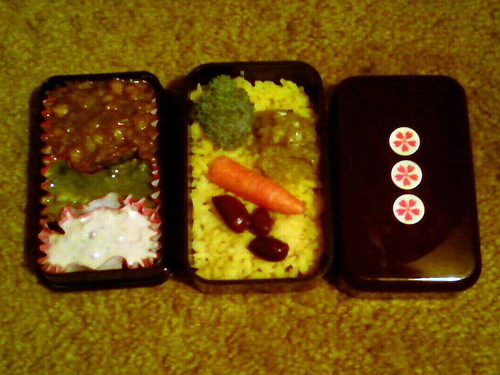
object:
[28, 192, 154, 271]
white sauce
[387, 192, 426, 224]
circles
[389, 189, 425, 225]
logo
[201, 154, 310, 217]
pizza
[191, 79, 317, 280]
rice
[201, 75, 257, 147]
greens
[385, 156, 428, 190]
white decal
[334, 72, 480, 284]
lid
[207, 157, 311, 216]
carrot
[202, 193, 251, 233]
olive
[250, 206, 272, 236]
olive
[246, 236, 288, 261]
olive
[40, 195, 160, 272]
food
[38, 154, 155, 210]
food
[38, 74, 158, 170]
food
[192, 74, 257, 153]
food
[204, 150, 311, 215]
food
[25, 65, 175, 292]
bowl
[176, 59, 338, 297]
bowl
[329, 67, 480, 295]
box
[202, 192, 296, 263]
three olives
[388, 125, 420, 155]
circle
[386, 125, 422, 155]
flower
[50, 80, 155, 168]
beans soup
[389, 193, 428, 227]
flowers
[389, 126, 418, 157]
decal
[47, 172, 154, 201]
sauce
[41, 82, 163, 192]
beans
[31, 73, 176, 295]
dish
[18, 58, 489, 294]
trays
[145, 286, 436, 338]
carpet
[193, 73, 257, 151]
curry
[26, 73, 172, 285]
container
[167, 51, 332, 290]
container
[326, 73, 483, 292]
container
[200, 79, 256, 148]
item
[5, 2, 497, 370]
table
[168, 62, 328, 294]
dish